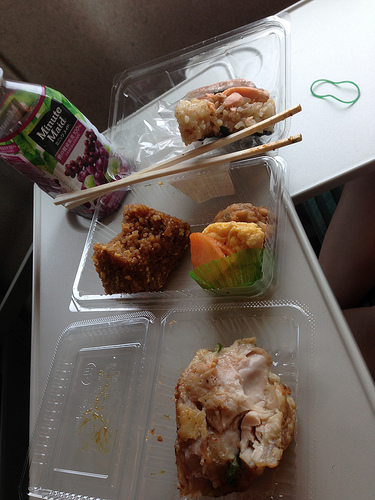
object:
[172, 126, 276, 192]
chopstick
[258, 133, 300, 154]
foot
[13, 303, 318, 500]
plastic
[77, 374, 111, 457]
sauce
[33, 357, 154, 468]
meat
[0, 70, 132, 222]
bottle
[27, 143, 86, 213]
logo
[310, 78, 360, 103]
band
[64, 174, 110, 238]
grapes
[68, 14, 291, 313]
box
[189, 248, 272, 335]
food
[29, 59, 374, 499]
tray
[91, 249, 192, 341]
food